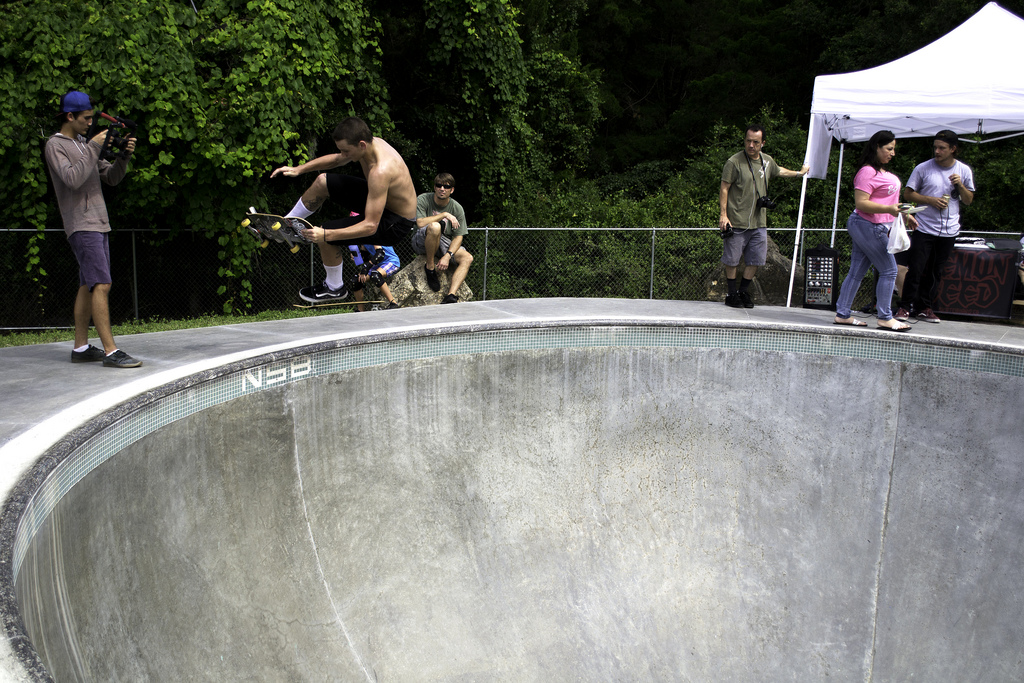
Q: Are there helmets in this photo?
A: No, there are no helmets.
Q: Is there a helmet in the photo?
A: No, there are no helmets.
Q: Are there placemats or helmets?
A: No, there are no helmets or placemats.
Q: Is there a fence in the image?
A: Yes, there is a fence.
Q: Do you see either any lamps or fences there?
A: Yes, there is a fence.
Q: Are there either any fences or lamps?
A: Yes, there is a fence.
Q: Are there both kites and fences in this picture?
A: No, there is a fence but no kites.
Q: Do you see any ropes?
A: No, there are no ropes.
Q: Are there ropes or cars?
A: No, there are no ropes or cars.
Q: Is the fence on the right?
A: No, the fence is on the left of the image.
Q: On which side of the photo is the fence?
A: The fence is on the left of the image.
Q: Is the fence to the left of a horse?
A: No, the fence is to the left of a man.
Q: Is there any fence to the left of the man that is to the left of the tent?
A: Yes, there is a fence to the left of the man.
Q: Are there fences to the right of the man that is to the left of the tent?
A: No, the fence is to the left of the man.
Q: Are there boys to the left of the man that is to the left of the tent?
A: No, there is a fence to the left of the man.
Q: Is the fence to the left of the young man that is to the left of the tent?
A: Yes, the fence is to the left of the man.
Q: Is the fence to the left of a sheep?
A: No, the fence is to the left of the man.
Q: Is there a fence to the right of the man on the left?
A: Yes, there is a fence to the right of the man.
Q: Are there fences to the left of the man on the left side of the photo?
A: No, the fence is to the right of the man.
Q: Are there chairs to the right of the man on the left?
A: No, there is a fence to the right of the man.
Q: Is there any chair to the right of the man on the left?
A: No, there is a fence to the right of the man.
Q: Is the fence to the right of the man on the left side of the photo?
A: Yes, the fence is to the right of the man.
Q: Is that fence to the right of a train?
A: No, the fence is to the right of the man.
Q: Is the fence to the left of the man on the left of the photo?
A: No, the fence is to the right of the man.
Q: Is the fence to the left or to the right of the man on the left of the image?
A: The fence is to the right of the man.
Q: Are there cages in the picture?
A: No, there are no cages.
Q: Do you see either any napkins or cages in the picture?
A: No, there are no cages or napkins.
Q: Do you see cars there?
A: No, there are no cars.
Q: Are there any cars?
A: No, there are no cars.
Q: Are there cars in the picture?
A: No, there are no cars.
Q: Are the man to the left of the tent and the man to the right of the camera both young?
A: Yes, both the man and the man are young.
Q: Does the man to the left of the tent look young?
A: Yes, the man is young.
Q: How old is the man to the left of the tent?
A: The man is young.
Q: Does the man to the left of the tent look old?
A: No, the man is young.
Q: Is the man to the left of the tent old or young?
A: The man is young.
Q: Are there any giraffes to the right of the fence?
A: No, there is a man to the right of the fence.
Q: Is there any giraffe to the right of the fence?
A: No, there is a man to the right of the fence.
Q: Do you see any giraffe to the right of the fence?
A: No, there is a man to the right of the fence.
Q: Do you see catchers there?
A: No, there are no catchers.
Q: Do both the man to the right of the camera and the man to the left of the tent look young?
A: Yes, both the man and the man are young.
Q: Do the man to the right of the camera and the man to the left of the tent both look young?
A: Yes, both the man and the man are young.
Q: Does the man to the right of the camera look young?
A: Yes, the man is young.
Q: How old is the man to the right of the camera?
A: The man is young.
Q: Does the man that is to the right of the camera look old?
A: No, the man is young.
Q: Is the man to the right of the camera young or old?
A: The man is young.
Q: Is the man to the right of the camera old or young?
A: The man is young.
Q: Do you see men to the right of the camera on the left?
A: Yes, there is a man to the right of the camera.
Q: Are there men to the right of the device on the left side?
A: Yes, there is a man to the right of the camera.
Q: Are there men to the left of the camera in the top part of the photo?
A: No, the man is to the right of the camera.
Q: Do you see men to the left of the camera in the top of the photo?
A: No, the man is to the right of the camera.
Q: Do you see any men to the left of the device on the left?
A: No, the man is to the right of the camera.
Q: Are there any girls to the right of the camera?
A: No, there is a man to the right of the camera.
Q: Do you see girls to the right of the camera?
A: No, there is a man to the right of the camera.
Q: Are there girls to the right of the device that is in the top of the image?
A: No, there is a man to the right of the camera.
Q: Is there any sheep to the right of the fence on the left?
A: No, there is a man to the right of the fence.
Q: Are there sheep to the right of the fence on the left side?
A: No, there is a man to the right of the fence.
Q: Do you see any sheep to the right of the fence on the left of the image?
A: No, there is a man to the right of the fence.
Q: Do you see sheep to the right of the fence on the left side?
A: No, there is a man to the right of the fence.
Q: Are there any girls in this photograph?
A: No, there are no girls.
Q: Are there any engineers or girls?
A: No, there are no girls or engineers.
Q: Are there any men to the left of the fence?
A: Yes, there is a man to the left of the fence.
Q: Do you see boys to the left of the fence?
A: No, there is a man to the left of the fence.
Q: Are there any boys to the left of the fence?
A: No, there is a man to the left of the fence.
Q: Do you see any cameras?
A: Yes, there is a camera.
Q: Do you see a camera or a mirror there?
A: Yes, there is a camera.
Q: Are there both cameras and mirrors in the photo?
A: No, there is a camera but no mirrors.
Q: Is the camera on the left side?
A: Yes, the camera is on the left of the image.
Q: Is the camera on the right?
A: No, the camera is on the left of the image.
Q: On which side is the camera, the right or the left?
A: The camera is on the left of the image.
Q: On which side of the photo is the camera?
A: The camera is on the left of the image.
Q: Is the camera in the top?
A: Yes, the camera is in the top of the image.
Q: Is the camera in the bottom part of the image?
A: No, the camera is in the top of the image.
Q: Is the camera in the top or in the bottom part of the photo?
A: The camera is in the top of the image.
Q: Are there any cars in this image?
A: No, there are no cars.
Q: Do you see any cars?
A: No, there are no cars.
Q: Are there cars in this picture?
A: No, there are no cars.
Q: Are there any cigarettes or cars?
A: No, there are no cars or cigarettes.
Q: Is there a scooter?
A: No, there are no scooters.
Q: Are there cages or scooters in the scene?
A: No, there are no scooters or cages.